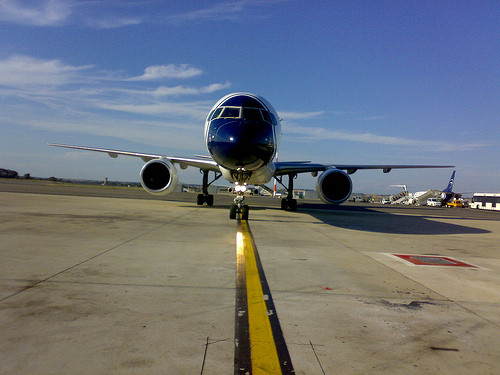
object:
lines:
[218, 213, 303, 373]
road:
[0, 188, 499, 371]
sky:
[0, 0, 499, 200]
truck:
[441, 199, 463, 211]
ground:
[270, 145, 348, 206]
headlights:
[230, 182, 249, 196]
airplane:
[80, 74, 458, 214]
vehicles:
[419, 191, 467, 212]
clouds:
[1, 0, 498, 189]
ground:
[377, 175, 416, 213]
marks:
[367, 289, 441, 321]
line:
[2, 272, 498, 306]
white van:
[426, 198, 441, 206]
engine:
[309, 154, 371, 218]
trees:
[2, 166, 30, 178]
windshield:
[215, 102, 242, 128]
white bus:
[472, 189, 499, 209]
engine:
[136, 157, 179, 195]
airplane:
[407, 169, 465, 205]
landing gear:
[229, 204, 251, 220]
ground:
[268, 217, 497, 372]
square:
[389, 253, 473, 268]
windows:
[206, 104, 276, 120]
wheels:
[195, 191, 296, 220]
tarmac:
[2, 168, 498, 237]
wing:
[35, 132, 220, 179]